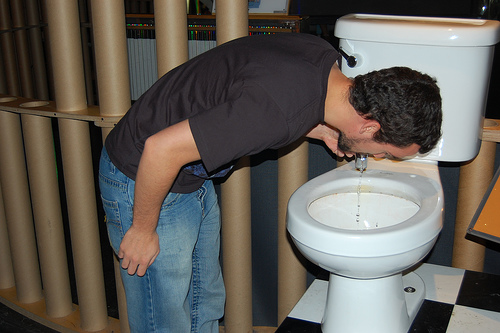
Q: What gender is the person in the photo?
A: Male.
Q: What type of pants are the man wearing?
A: Blue jeans.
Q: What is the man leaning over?
A: Toilet bowl.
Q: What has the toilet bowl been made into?
A: Water fountain.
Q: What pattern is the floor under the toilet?
A: Checkered.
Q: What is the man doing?
A: Bending over.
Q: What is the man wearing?
A: A t shirt.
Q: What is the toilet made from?
A: Porcelain.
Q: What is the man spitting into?
A: Toilet.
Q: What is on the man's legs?
A: Jeans.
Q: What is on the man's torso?
A: T Shirt.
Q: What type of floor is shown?
A: Tile.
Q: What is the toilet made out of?
A: White porcelain.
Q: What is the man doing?
A: Spitting.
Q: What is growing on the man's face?
A: Beard.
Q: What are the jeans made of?
A: Denim.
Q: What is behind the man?
A: Tan bars.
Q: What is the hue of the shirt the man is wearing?
A: Black.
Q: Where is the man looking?
A: In the toilet.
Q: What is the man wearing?
A: Jeans.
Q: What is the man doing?
A: Looking at the toilet .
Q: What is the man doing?
A: Drinking from the toilet.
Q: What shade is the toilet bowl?
A: White.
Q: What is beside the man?
A: Brown tubes.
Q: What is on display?
A: Toilet.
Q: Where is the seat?
A: No seat.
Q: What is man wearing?
A: Jeans.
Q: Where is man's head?
A: Over toilet.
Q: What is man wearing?
A: Gray shirt.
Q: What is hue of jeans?
A: Blue.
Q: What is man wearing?
A: Jeans.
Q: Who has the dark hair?
A: A man.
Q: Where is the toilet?
A: Bathroom.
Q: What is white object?
A: Toilet.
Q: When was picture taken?
A: Daytime.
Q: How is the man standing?
A: Bent over.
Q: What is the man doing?
A: Spitting in toilet.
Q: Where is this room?
A: Restroom.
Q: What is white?
A: Toilet.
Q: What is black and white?
A: The floor.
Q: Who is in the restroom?
A: A man.